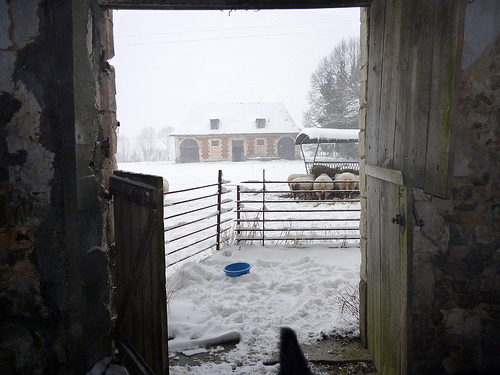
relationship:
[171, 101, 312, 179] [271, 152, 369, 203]
home behind sheep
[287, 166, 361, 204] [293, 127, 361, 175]
animals feeding from trough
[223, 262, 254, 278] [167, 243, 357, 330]
bowl laying in snow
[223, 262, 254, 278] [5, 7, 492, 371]
bowl near barn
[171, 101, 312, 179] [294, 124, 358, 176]
home in front of troft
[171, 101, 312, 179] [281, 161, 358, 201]
home in front of animals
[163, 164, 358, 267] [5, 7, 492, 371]
fencing in front of barn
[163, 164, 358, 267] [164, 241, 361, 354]
fencing in snow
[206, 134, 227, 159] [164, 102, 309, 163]
door on house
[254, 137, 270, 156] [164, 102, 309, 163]
door on house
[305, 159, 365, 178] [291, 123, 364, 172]
hay in trough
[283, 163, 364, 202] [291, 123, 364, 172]
sheep are at trough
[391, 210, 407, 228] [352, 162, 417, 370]
knob on door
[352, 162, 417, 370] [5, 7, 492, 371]
door on barn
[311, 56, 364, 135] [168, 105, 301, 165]
tree next to house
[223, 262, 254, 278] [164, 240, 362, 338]
bowl on ground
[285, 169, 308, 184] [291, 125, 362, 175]
sheep at troft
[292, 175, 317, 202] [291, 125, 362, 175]
sheep at troft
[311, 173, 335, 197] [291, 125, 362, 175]
sheep at troft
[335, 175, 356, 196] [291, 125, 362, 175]
sheep at troft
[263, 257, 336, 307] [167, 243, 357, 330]
tracks are in snow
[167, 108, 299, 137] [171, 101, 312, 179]
roof on home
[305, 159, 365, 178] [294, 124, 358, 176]
hay in troft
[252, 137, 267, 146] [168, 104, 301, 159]
window on building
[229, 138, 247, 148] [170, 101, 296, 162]
window on building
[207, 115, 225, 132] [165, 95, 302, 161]
window on building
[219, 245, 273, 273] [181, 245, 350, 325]
bowl in snow